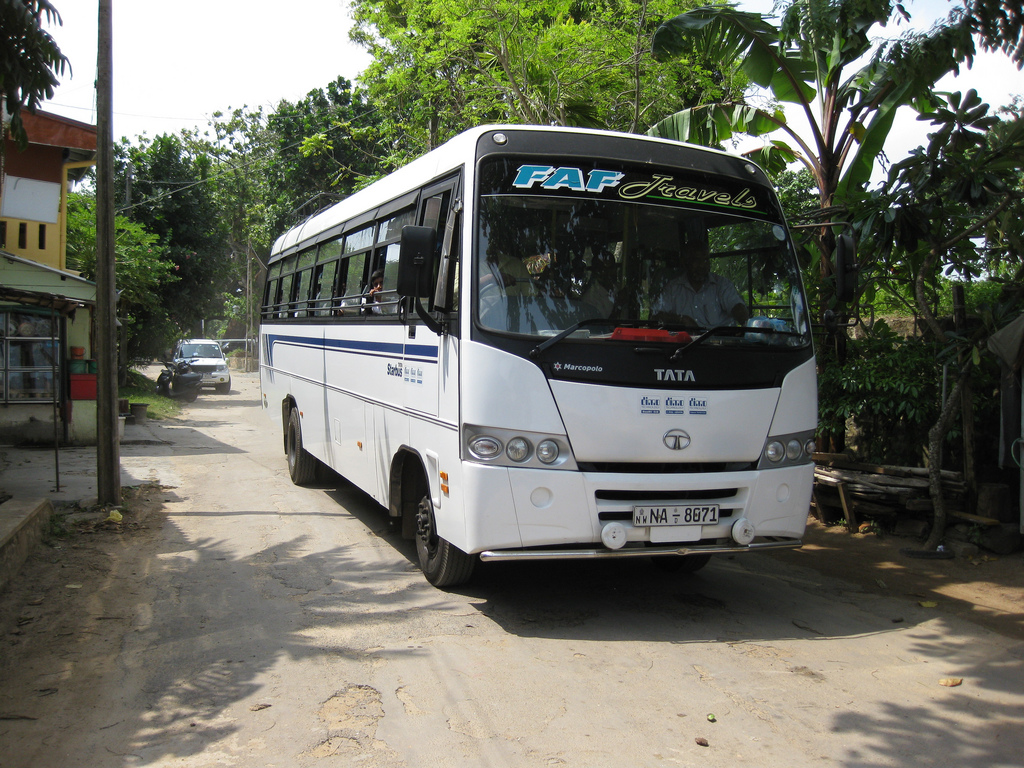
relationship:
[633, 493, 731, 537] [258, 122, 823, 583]
license plate on bus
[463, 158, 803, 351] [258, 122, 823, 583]
windshield on bus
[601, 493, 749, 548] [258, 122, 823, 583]
grate on front bus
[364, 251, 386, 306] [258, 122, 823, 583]
window on bus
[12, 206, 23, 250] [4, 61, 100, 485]
window on building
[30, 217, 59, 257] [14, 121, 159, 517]
window on building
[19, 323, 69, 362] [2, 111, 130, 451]
window on building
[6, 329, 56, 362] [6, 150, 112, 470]
window on building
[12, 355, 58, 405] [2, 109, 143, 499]
window on building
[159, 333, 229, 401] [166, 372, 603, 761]
car on street